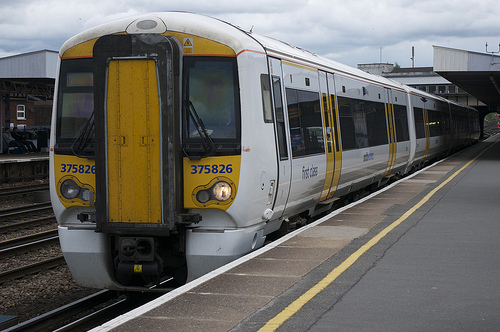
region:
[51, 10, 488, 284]
a white and yellow train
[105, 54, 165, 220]
the yellow front door on the train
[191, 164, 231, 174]
the number on the train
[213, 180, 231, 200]
the head light of the train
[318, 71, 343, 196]
the passenger doors on the train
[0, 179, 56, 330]
the train tracks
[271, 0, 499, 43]
a cloud in the sky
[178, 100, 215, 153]
the windshield wiper on the train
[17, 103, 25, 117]
a window on the building in the distance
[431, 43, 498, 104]
the hanger on the platform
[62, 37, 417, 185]
white and yellow passenger train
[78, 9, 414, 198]
train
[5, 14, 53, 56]
white clouds in blue sky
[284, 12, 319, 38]
white clouds in blue sky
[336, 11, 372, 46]
white clouds in blue sky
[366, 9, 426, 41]
white clouds in blue sky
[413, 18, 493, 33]
white clouds in blue sky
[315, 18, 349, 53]
white clouds in blue sky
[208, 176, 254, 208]
orange light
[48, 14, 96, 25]
white clouds in blue sky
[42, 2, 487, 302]
a train at the station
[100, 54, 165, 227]
a door at the front of the train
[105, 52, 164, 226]
the door is yellow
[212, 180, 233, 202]
the right light is on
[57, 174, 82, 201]
the left light is off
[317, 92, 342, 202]
the side doors are closed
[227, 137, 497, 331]
a yellow line on the ground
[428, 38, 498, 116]
a roof over the station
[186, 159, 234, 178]
a number on the front of the train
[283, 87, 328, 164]
a window on the side of the train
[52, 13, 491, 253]
a yellow and white train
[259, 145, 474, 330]
yellow line on the pavement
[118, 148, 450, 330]
white line on pavement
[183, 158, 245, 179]
blue numbers on the train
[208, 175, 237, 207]
one headlight is on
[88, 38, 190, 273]
a yellow door on the end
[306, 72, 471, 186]
three yellow doors on the side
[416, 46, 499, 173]
a shadow cast on train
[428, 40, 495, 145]
an awning for passengers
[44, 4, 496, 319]
a long passenger train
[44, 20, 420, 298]
a large train on the train tracks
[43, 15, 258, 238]
the black, yellow and white lead car of the train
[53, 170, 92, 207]
a burned out headlight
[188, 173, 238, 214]
a working headlight on the front of the train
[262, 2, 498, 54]
billowy white clouds in the sky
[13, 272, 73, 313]
collection of rocks and gravel between the tracks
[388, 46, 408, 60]
light blue sky peeking through the clouds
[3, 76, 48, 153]
a one story brick building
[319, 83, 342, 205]
yellow doors to the first class train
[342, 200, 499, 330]
concrete walkway for train traffic